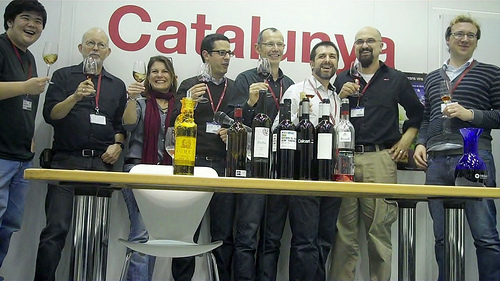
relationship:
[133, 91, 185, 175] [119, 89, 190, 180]
part of sweater